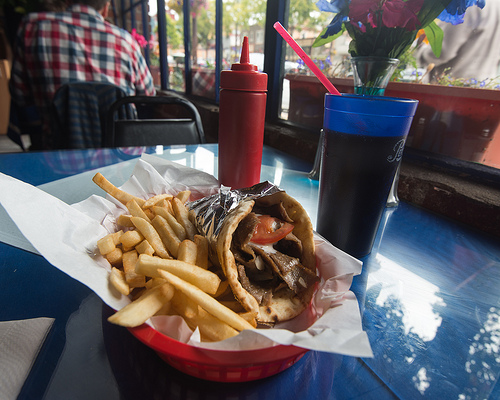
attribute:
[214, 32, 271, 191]
bottle — red, ketchup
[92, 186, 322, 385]
container — red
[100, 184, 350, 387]
container — red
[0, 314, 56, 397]
napkin — white, folded, paper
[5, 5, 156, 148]
shirt — checkered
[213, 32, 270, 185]
container — red, plastic, ketchup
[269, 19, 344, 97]
straw — red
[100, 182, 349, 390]
basket — red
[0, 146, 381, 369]
paper — white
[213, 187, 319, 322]
bread — flat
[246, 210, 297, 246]
tomato — red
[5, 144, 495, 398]
table — blue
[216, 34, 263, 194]
ketchup bottle — red 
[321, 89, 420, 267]
cup — blue, plastic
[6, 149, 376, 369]
thin paper — thin 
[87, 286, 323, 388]
red basket — red 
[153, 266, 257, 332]
french fry — fresh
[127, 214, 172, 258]
french fry — fresh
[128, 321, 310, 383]
basket — red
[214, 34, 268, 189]
ketchup container — plastic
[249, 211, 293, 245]
tomato slice — red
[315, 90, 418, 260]
cup — blue, plastic, dark blue, tall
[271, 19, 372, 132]
straw — red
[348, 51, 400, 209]
vase — glass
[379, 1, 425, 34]
flower — colored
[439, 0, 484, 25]
flower — colored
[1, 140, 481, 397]
tabletop — blue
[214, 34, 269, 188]
ketchup bottle — red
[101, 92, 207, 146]
chair — black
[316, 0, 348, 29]
flower — colored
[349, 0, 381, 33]
flower — colored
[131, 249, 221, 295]
french fry — fresh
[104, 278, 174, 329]
french fry — fresh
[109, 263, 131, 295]
french fry — fresh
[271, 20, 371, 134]
drinking straw — red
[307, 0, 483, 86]
flowers — fake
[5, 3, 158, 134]
shirt — plaid